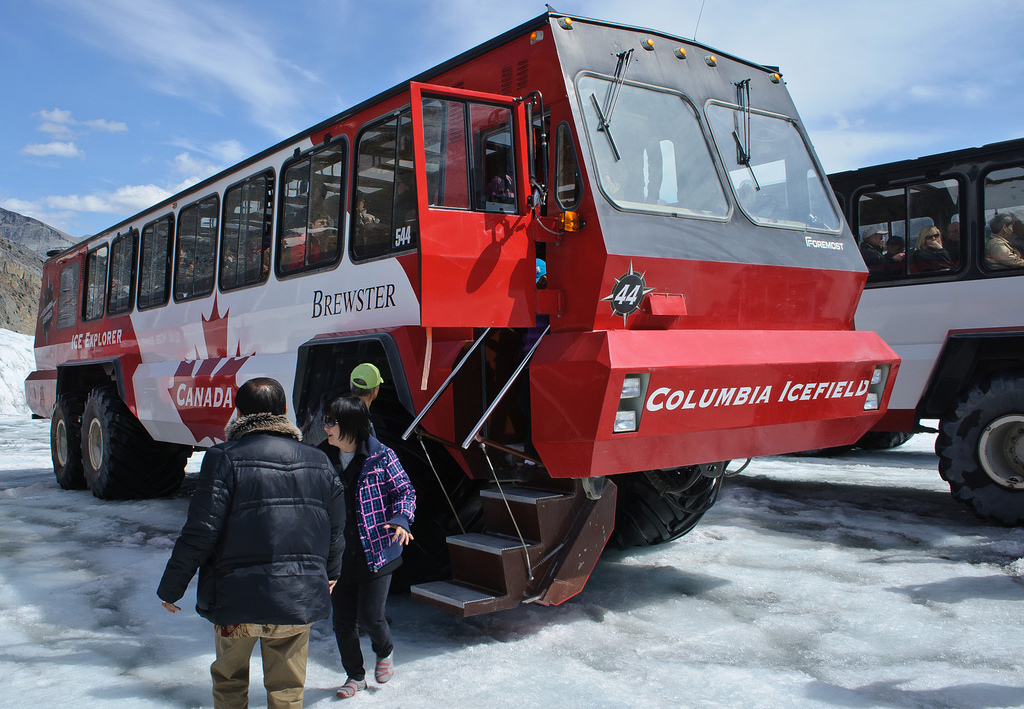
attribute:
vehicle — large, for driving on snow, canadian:
[25, 11, 903, 631]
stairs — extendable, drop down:
[408, 463, 619, 636]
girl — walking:
[316, 394, 421, 703]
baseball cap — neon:
[346, 361, 384, 391]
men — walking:
[156, 375, 344, 708]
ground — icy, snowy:
[2, 327, 1022, 704]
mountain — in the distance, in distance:
[1, 203, 92, 360]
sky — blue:
[2, 4, 1023, 244]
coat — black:
[156, 415, 348, 628]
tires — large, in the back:
[77, 388, 189, 507]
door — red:
[408, 78, 537, 340]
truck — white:
[815, 136, 1023, 525]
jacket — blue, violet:
[321, 440, 417, 573]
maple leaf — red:
[160, 292, 254, 446]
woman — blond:
[912, 225, 953, 271]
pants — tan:
[209, 620, 311, 708]